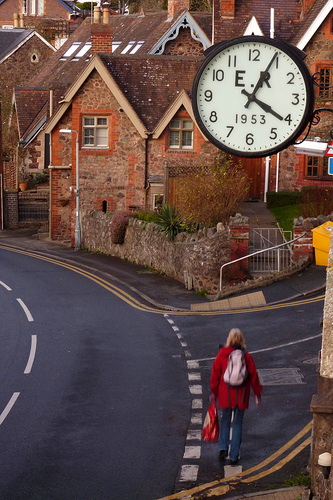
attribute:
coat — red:
[197, 342, 271, 413]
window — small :
[167, 118, 193, 149]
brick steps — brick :
[18, 190, 48, 228]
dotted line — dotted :
[163, 309, 203, 499]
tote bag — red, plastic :
[202, 400, 220, 445]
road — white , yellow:
[6, 248, 208, 486]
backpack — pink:
[222, 349, 247, 385]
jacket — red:
[209, 345, 259, 411]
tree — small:
[143, 200, 191, 247]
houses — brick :
[1, 0, 331, 301]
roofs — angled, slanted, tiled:
[2, 2, 332, 143]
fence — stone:
[77, 206, 239, 290]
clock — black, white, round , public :
[187, 35, 317, 157]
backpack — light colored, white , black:
[222, 348, 249, 387]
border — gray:
[157, 29, 202, 53]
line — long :
[1, 244, 324, 315]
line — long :
[156, 418, 312, 497]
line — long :
[160, 312, 203, 496]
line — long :
[0, 280, 37, 425]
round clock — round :
[196, 38, 307, 155]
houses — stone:
[16, 2, 315, 273]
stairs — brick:
[16, 172, 74, 230]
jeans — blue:
[219, 406, 242, 461]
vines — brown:
[105, 204, 127, 243]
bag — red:
[200, 398, 219, 443]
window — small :
[82, 113, 111, 146]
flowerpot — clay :
[17, 184, 27, 192]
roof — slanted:
[3, 10, 188, 113]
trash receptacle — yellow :
[312, 220, 331, 267]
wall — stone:
[71, 206, 228, 291]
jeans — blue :
[212, 397, 247, 466]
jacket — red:
[204, 343, 265, 404]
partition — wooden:
[161, 161, 230, 226]